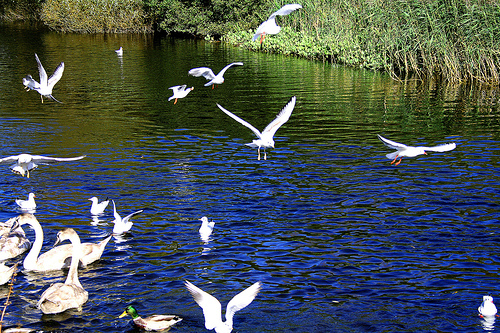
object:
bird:
[20, 52, 67, 104]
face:
[125, 304, 139, 318]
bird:
[86, 196, 109, 217]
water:
[0, 33, 499, 332]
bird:
[196, 215, 217, 241]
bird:
[474, 294, 500, 320]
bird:
[115, 305, 182, 332]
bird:
[37, 227, 93, 320]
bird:
[112, 46, 123, 59]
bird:
[213, 94, 297, 162]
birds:
[371, 131, 461, 169]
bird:
[167, 83, 195, 105]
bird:
[0, 152, 87, 179]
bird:
[109, 199, 143, 235]